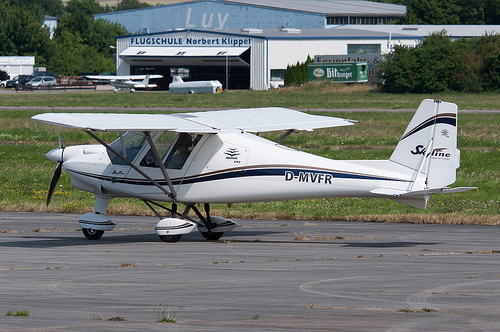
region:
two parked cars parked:
[4, 68, 59, 92]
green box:
[305, 53, 377, 85]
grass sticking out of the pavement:
[0, 198, 499, 327]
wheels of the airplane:
[78, 217, 225, 244]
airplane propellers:
[38, 119, 77, 205]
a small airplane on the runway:
[21, 93, 479, 240]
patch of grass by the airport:
[2, 88, 498, 220]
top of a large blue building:
[42, 1, 404, 30]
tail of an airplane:
[387, 94, 479, 211]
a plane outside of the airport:
[87, 64, 162, 91]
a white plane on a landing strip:
[20, 80, 466, 242]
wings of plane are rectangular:
[20, 90, 355, 140]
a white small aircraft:
[20, 80, 475, 236]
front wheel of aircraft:
[70, 205, 116, 245]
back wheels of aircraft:
[151, 208, 241, 246]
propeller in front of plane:
[37, 120, 73, 207]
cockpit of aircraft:
[101, 128, 208, 180]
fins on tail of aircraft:
[392, 88, 486, 214]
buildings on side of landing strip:
[29, 3, 499, 88]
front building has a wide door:
[108, 30, 272, 91]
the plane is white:
[63, 97, 450, 245]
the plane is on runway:
[23, 87, 434, 278]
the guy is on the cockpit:
[158, 139, 215, 183]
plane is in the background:
[95, 63, 187, 115]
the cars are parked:
[12, 63, 65, 103]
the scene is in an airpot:
[6, 8, 498, 314]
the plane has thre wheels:
[23, 95, 474, 257]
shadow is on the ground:
[343, 221, 421, 273]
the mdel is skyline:
[389, 133, 461, 167]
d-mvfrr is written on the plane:
[271, 160, 342, 197]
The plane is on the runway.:
[43, 82, 498, 265]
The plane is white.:
[25, 87, 439, 204]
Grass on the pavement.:
[103, 297, 198, 328]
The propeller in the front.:
[26, 126, 78, 211]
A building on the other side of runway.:
[83, 5, 357, 100]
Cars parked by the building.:
[10, 63, 82, 100]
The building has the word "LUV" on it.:
[171, 1, 263, 39]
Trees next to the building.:
[26, 14, 144, 87]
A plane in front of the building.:
[77, 52, 181, 112]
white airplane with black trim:
[27, 90, 476, 244]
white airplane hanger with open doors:
[106, 31, 496, 91]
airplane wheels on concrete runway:
[1, 209, 497, 329]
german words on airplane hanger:
[129, 37, 254, 48]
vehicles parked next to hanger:
[2, 64, 84, 99]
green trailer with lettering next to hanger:
[303, 56, 374, 86]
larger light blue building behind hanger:
[41, 3, 416, 55]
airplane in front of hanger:
[85, 27, 166, 102]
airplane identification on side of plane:
[273, 159, 341, 194]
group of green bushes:
[356, 34, 496, 96]